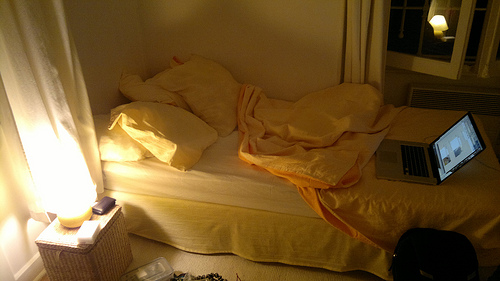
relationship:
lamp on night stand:
[23, 162, 95, 231] [34, 202, 134, 279]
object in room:
[389, 222, 488, 279] [0, 0, 497, 277]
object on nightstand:
[88, 195, 115, 216] [37, 198, 134, 280]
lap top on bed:
[374, 112, 484, 187] [95, 53, 496, 276]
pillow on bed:
[106, 99, 217, 174] [111, 82, 361, 219]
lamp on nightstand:
[23, 162, 95, 231] [34, 205, 143, 279]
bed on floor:
[114, 69, 496, 235] [68, 252, 498, 279]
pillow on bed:
[106, 99, 217, 174] [95, 53, 496, 276]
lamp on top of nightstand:
[32, 152, 98, 227] [25, 201, 170, 276]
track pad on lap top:
[378, 147, 398, 167] [374, 112, 484, 187]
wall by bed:
[136, 3, 346, 102] [93, 88, 498, 275]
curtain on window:
[0, 2, 111, 222] [386, 1, 467, 80]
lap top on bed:
[370, 112, 484, 184] [93, 88, 498, 275]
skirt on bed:
[100, 190, 394, 280] [95, 53, 496, 276]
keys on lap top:
[399, 139, 429, 179] [374, 112, 484, 187]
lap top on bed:
[374, 112, 484, 187] [110, 65, 457, 250]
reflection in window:
[422, 10, 454, 36] [387, 1, 474, 83]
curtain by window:
[349, 6, 387, 92] [390, 0, 472, 89]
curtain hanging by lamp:
[0, 2, 111, 222] [14, 121, 99, 259]